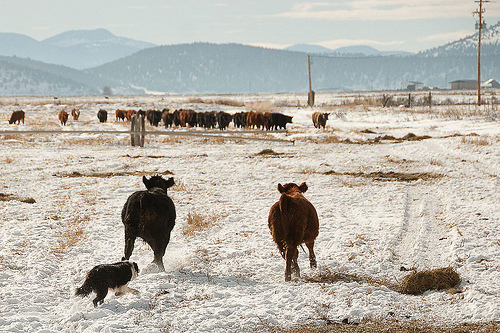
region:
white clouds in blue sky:
[12, 8, 48, 33]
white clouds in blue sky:
[316, 26, 369, 75]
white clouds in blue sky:
[177, 15, 240, 73]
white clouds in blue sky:
[239, 18, 289, 97]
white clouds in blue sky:
[66, 15, 145, 65]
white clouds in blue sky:
[129, 13, 243, 116]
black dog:
[62, 254, 144, 312]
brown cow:
[115, 161, 186, 245]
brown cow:
[253, 164, 329, 268]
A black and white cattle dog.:
[73, 255, 143, 310]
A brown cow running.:
[265, 176, 322, 281]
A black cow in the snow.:
[120, 172, 179, 271]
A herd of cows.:
[113, 105, 303, 132]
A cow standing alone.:
[311, 109, 331, 129]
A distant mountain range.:
[0, 20, 499, 97]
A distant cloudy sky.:
[1, 1, 499, 50]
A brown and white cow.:
[70, 106, 83, 119]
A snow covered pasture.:
[0, 89, 499, 331]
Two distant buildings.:
[448, 77, 498, 90]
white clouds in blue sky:
[39, 25, 61, 55]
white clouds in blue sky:
[361, 21, 403, 57]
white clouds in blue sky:
[275, 13, 333, 44]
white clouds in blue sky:
[189, 30, 236, 60]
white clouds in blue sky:
[120, 22, 188, 60]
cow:
[105, 173, 196, 251]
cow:
[260, 175, 317, 262]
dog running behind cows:
[48, 250, 136, 298]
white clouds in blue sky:
[22, 0, 104, 97]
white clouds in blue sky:
[75, 17, 107, 53]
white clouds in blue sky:
[368, 35, 400, 76]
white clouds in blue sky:
[270, 8, 330, 64]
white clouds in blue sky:
[372, 5, 438, 82]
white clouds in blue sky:
[141, 17, 201, 67]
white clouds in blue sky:
[207, 19, 265, 70]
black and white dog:
[91, 257, 140, 309]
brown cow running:
[269, 171, 335, 263]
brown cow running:
[107, 168, 197, 263]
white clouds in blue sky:
[18, 24, 56, 71]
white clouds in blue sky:
[339, 22, 391, 72]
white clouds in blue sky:
[348, 13, 419, 43]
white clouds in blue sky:
[221, 16, 282, 60]